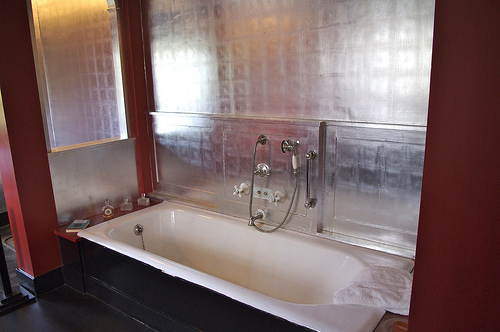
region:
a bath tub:
[99, 128, 356, 324]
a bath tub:
[30, 11, 284, 325]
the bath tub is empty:
[92, 169, 322, 324]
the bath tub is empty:
[80, 94, 263, 313]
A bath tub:
[122, 164, 309, 322]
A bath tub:
[221, 198, 313, 319]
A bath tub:
[191, 205, 262, 305]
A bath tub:
[140, 184, 238, 308]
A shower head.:
[228, 132, 323, 242]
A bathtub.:
[91, 197, 386, 329]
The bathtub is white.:
[72, 195, 392, 328]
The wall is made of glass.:
[158, 7, 224, 174]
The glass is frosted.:
[158, 10, 225, 172]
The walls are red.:
[1, 53, 66, 268]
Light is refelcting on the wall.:
[158, 25, 235, 184]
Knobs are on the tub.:
[210, 125, 325, 240]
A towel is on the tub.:
[317, 243, 424, 320]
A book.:
[53, 212, 100, 243]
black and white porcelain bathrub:
[68, 195, 399, 330]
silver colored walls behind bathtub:
[146, 23, 417, 249]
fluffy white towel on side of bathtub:
[331, 259, 415, 316]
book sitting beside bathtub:
[65, 211, 92, 233]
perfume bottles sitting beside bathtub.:
[96, 195, 153, 217]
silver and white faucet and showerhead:
[232, 134, 302, 232]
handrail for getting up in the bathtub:
[299, 148, 319, 213]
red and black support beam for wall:
[0, 0, 54, 290]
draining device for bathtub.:
[129, 223, 156, 255]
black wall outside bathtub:
[54, 232, 335, 324]